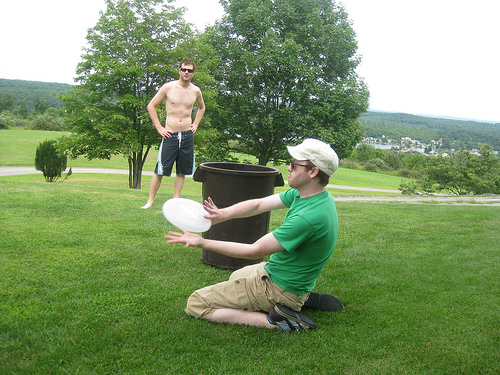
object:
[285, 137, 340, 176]
hat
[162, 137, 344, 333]
man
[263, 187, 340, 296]
shirt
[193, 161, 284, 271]
garbage can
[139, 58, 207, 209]
man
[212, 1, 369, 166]
tree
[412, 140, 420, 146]
building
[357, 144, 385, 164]
tree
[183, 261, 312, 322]
pants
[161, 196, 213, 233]
frisbee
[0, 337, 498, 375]
grass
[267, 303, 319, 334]
shoe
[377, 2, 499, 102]
sky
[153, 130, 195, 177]
shorts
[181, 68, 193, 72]
sunglasses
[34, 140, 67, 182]
bush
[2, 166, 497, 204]
sidewalk